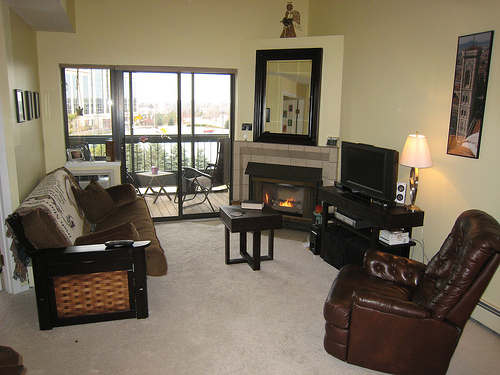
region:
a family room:
[6, 19, 497, 373]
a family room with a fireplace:
[14, 0, 498, 374]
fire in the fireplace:
[278, 196, 292, 207]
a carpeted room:
[16, 31, 493, 373]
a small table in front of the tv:
[213, 196, 288, 277]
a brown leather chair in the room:
[318, 207, 498, 373]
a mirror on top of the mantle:
[248, 40, 325, 148]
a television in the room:
[334, 137, 402, 204]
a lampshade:
[395, 128, 436, 218]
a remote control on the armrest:
[101, 236, 135, 248]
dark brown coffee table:
[223, 203, 280, 266]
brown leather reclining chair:
[324, 214, 496, 374]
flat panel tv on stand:
[338, 138, 396, 207]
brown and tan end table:
[29, 238, 151, 324]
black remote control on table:
[103, 238, 133, 247]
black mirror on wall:
[257, 48, 322, 143]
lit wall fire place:
[247, 159, 316, 216]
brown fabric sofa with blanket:
[22, 165, 169, 270]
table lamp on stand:
[398, 130, 425, 214]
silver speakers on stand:
[396, 180, 406, 205]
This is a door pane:
[181, 67, 232, 214]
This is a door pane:
[129, 67, 182, 219]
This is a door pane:
[61, 66, 133, 201]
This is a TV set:
[329, 124, 408, 210]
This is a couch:
[9, 158, 173, 337]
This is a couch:
[312, 208, 497, 367]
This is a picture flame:
[14, 80, 24, 131]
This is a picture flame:
[25, 81, 35, 128]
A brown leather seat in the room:
[319, 213, 493, 360]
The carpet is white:
[184, 282, 274, 366]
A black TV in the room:
[340, 141, 392, 191]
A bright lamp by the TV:
[403, 131, 425, 208]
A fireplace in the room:
[251, 172, 308, 214]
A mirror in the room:
[256, 52, 315, 138]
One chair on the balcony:
[185, 140, 231, 209]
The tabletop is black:
[222, 203, 277, 226]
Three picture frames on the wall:
[14, 88, 40, 120]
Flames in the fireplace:
[281, 195, 296, 207]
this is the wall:
[355, 9, 412, 96]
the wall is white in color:
[359, 22, 428, 109]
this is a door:
[63, 68, 235, 163]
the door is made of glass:
[136, 77, 169, 129]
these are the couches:
[26, 195, 499, 372]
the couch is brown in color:
[378, 260, 400, 300]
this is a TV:
[336, 139, 396, 201]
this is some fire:
[266, 190, 296, 207]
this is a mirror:
[266, 59, 311, 131]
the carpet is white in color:
[212, 305, 242, 329]